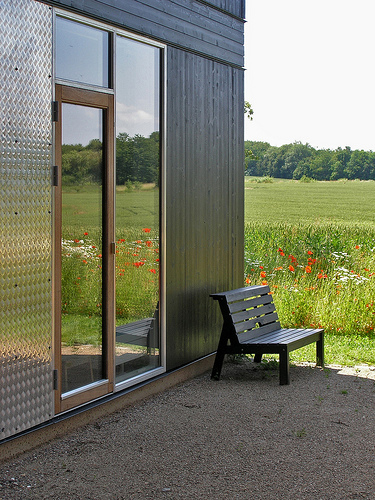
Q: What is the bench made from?
A: Wood.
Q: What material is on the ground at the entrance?
A: Gravel.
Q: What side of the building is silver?
A: The left side.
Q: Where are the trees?
A: In the backgroud.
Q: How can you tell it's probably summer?
A: Flowers are blooming.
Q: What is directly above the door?
A: A window.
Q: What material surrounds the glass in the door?
A: Wood.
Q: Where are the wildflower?
A: Next to the building?.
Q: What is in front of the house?
A: A bench.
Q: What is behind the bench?
A: A house.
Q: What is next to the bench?
A: Doors.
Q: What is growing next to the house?
A: Grass.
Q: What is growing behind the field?
A: Trees.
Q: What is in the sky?
A: Clouds.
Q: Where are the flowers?
A: In the field.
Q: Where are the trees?
A: Meadow.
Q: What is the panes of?
A: Glass.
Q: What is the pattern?
A: Diamond.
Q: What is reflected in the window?
A: Countryside.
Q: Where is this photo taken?
A: Country area.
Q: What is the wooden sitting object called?
A: Bench.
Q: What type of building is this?
A: House.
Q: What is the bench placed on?
A: Sand.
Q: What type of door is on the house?
A: Glass.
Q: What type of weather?
A: Clear.